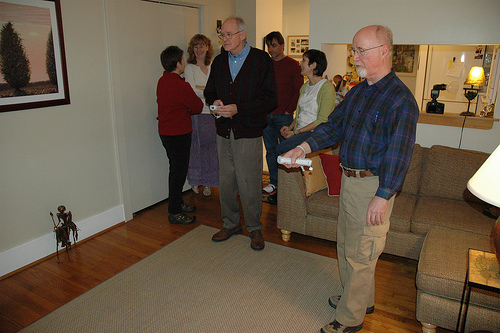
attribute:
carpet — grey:
[1, 219, 347, 331]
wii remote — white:
[277, 156, 313, 166]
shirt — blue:
[225, 43, 249, 83]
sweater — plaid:
[210, 59, 262, 101]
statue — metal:
[43, 201, 83, 263]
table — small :
[453, 244, 499, 331]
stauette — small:
[38, 195, 90, 271]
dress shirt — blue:
[301, 67, 420, 199]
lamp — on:
[459, 59, 483, 122]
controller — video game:
[275, 158, 312, 168]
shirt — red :
[156, 74, 204, 138]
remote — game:
[264, 136, 375, 187]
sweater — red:
[154, 70, 203, 133]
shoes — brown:
[315, 292, 371, 330]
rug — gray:
[20, 222, 362, 329]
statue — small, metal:
[50, 201, 80, 262]